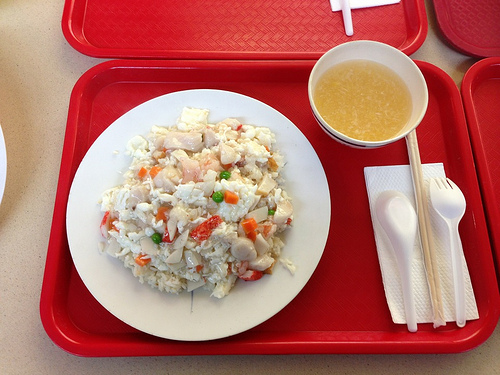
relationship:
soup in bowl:
[338, 77, 396, 121] [306, 37, 431, 151]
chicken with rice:
[174, 152, 196, 185] [136, 141, 162, 166]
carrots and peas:
[242, 217, 273, 241] [213, 169, 233, 206]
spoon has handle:
[377, 190, 420, 333] [401, 255, 421, 334]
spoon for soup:
[377, 190, 420, 333] [338, 77, 396, 121]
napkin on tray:
[363, 162, 479, 326] [38, 59, 500, 358]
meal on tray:
[111, 134, 298, 291] [38, 59, 500, 358]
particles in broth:
[375, 71, 388, 86] [328, 72, 361, 120]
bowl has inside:
[306, 37, 431, 151] [354, 57, 415, 88]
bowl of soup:
[306, 37, 431, 151] [338, 77, 396, 121]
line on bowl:
[310, 111, 366, 150] [306, 37, 431, 151]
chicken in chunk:
[174, 152, 196, 185] [221, 144, 235, 165]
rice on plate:
[136, 141, 162, 166] [64, 88, 333, 343]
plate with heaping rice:
[64, 88, 333, 343] [136, 141, 162, 166]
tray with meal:
[38, 59, 500, 358] [97, 105, 297, 300]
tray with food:
[38, 59, 500, 358] [231, 154, 271, 213]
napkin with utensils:
[363, 162, 479, 326] [381, 129, 468, 332]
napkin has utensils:
[363, 162, 479, 326] [381, 129, 468, 332]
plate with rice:
[64, 88, 333, 343] [136, 141, 162, 166]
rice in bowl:
[136, 141, 162, 166] [307, 39, 430, 150]